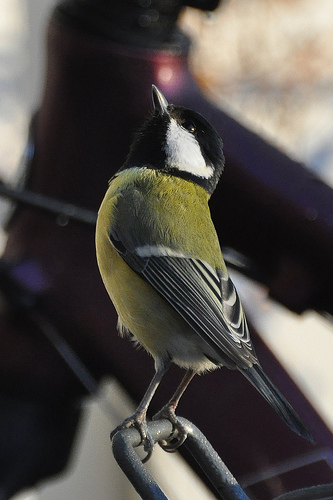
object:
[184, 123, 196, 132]
eye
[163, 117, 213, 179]
spot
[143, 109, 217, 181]
face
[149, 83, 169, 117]
mouth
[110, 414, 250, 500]
handle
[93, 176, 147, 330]
belly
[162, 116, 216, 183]
cheek feathers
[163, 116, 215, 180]
skin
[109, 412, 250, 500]
wire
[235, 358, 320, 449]
bird tail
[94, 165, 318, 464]
feathers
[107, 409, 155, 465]
talon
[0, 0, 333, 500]
background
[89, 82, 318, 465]
image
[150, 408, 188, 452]
claw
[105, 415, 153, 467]
claw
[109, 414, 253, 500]
iron stand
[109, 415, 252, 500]
metal hook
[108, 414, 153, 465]
hook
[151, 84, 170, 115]
beak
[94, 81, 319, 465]
bird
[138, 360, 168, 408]
leg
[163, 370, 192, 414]
leg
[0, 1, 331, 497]
object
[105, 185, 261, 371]
wing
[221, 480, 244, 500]
metal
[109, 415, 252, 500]
stand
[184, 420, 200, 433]
light